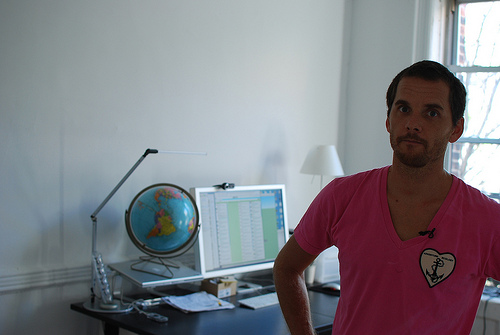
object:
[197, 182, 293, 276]
monitor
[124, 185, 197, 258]
globe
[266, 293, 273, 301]
key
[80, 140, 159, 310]
tall lamp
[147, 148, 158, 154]
led bulbs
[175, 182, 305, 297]
screen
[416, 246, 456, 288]
heart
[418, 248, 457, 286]
anchor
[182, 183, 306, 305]
computer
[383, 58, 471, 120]
hair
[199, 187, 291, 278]
frame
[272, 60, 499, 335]
man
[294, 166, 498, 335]
shirt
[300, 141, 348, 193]
lamp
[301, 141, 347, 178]
shade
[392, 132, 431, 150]
moustache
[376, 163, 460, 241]
vee neck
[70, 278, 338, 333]
desk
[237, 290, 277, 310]
keyboard